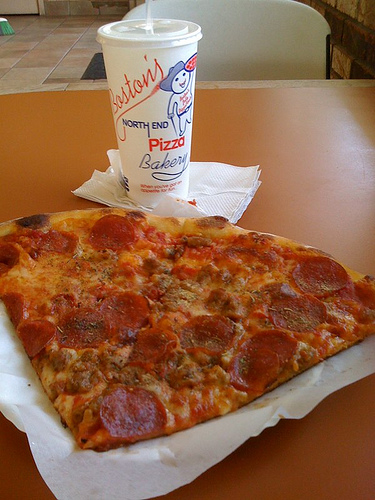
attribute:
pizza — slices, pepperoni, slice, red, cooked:
[49, 238, 295, 409]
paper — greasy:
[82, 453, 164, 482]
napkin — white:
[208, 156, 261, 213]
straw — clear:
[144, 0, 160, 15]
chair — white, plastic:
[232, 5, 308, 76]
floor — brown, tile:
[42, 26, 63, 37]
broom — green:
[4, 22, 18, 42]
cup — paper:
[107, 32, 192, 198]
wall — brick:
[347, 0, 361, 53]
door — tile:
[15, 1, 39, 11]